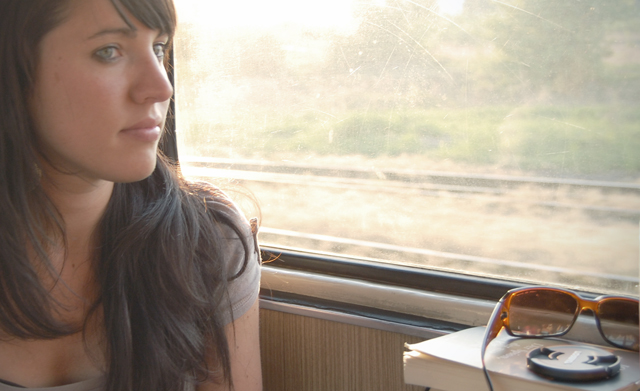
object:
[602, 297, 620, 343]
lens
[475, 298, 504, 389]
arm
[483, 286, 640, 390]
glasses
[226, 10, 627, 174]
trees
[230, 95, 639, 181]
bushes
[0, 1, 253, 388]
lady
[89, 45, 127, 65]
eyes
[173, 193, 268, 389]
arm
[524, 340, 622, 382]
coffee mug-lid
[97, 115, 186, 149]
lips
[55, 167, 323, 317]
shoulder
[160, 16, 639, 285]
window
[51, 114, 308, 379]
hair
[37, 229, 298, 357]
shirt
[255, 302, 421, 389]
wall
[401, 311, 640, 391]
book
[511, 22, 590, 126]
leaves